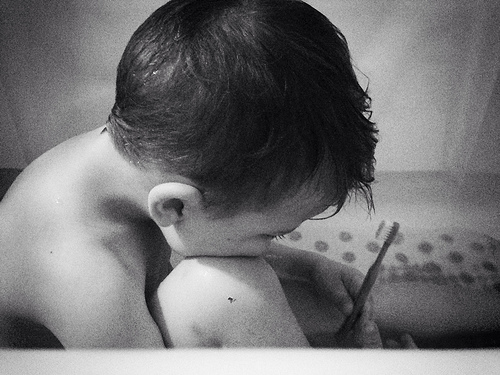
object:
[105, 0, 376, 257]
head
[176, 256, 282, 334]
knee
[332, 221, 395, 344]
toothbrush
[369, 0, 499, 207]
curtain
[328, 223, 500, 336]
dots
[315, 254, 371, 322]
hand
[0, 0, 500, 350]
boy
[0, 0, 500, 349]
bathroom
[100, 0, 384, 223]
hair